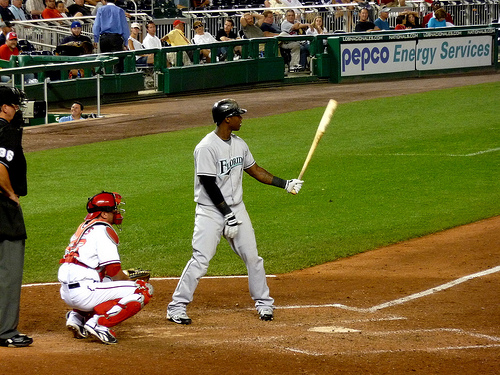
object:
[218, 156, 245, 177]
marlins logo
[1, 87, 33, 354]
baseball umpire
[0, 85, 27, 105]
black hat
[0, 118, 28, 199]
black shirt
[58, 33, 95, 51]
black shirt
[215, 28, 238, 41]
black shirt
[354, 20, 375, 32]
black shirt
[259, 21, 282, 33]
black shirt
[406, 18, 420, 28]
black shirt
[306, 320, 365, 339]
home base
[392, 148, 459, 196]
ground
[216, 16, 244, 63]
man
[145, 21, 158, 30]
black hair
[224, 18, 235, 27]
black hair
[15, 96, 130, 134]
dugout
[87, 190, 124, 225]
helmet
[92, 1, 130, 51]
man shirt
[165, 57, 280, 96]
wall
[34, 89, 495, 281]
grass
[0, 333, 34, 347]
shoe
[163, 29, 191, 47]
shirt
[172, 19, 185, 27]
hat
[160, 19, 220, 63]
fans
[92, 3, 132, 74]
man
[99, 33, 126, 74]
pants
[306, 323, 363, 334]
plate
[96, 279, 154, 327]
knee guards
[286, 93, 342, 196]
baseball bat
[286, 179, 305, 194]
hand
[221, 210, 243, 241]
baseball glove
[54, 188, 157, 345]
catcher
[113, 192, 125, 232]
mask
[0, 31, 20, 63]
man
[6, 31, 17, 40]
hat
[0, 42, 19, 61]
shirt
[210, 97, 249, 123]
baseball cap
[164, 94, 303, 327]
batter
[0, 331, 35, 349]
dress shoes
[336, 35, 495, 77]
advertising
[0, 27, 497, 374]
game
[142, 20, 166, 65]
fan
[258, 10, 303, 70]
fan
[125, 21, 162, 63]
fan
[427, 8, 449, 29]
fan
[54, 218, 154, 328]
uniform